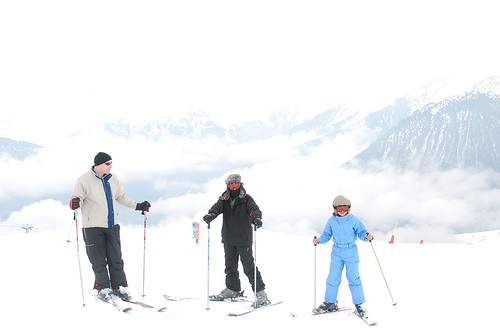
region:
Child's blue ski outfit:
[315, 214, 377, 309]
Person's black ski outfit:
[200, 187, 284, 294]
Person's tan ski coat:
[60, 169, 147, 233]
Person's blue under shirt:
[88, 167, 123, 230]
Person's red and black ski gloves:
[58, 194, 159, 219]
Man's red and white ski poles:
[57, 207, 155, 310]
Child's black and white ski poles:
[302, 235, 406, 316]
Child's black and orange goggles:
[328, 202, 363, 216]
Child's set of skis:
[284, 291, 395, 331]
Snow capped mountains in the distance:
[85, 87, 496, 216]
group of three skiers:
[55, 125, 395, 315]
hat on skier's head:
[331, 192, 353, 224]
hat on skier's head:
[219, 169, 250, 199]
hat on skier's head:
[96, 150, 116, 171]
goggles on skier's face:
[103, 163, 118, 173]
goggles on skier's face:
[221, 180, 241, 190]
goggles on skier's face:
[330, 204, 352, 214]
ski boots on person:
[248, 288, 270, 308]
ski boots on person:
[219, 284, 244, 299]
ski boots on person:
[99, 287, 116, 304]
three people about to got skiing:
[63, 128, 389, 325]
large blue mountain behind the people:
[397, 102, 487, 159]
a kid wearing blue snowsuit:
[311, 189, 396, 326]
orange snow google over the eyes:
[333, 206, 356, 214]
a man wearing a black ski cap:
[49, 154, 157, 309]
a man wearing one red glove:
[59, 142, 157, 317]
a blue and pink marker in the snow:
[183, 217, 200, 245]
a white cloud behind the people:
[370, 170, 486, 227]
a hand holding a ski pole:
[303, 230, 323, 245]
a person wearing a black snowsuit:
[194, 180, 276, 331]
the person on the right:
[302, 190, 378, 325]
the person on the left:
[61, 148, 158, 305]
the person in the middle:
[198, 168, 278, 310]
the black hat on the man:
[87, 147, 117, 167]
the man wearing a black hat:
[60, 148, 160, 303]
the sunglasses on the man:
[100, 159, 116, 168]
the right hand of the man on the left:
[67, 192, 84, 214]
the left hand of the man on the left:
[132, 195, 154, 216]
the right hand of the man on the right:
[307, 229, 322, 250]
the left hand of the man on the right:
[356, 225, 377, 246]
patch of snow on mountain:
[398, 93, 487, 170]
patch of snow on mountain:
[426, 105, 444, 123]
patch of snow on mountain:
[471, 83, 491, 100]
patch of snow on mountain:
[373, 145, 389, 159]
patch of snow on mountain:
[451, 153, 473, 183]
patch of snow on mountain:
[383, 115, 393, 123]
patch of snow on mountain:
[336, 100, 359, 117]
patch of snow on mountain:
[305, 135, 322, 153]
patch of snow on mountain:
[177, 116, 208, 135]